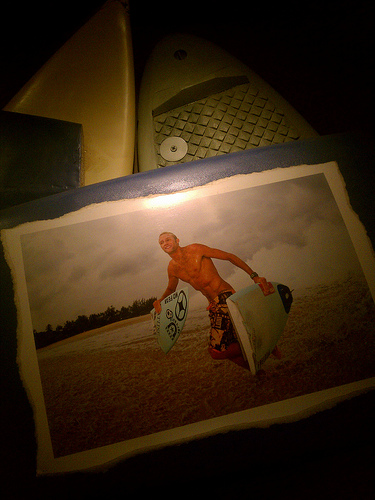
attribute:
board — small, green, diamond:
[148, 60, 231, 154]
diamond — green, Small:
[192, 122, 208, 135]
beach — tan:
[59, 334, 211, 398]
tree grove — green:
[30, 294, 155, 350]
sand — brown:
[33, 278, 373, 460]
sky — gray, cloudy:
[19, 170, 358, 335]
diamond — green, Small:
[188, 99, 226, 119]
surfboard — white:
[140, 283, 306, 346]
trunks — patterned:
[202, 289, 245, 352]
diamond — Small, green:
[209, 105, 248, 131]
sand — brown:
[305, 303, 359, 360]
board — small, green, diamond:
[148, 70, 328, 162]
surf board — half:
[126, 241, 337, 387]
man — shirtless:
[144, 224, 270, 374]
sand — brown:
[75, 347, 210, 412]